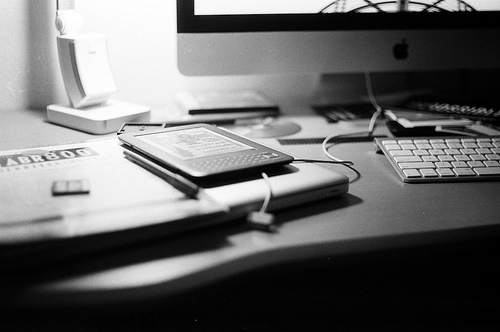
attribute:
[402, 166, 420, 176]
keys — white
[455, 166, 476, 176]
keys — white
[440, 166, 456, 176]
keys — white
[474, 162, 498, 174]
keys — white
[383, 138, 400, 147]
keys — white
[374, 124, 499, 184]
keyboard — light colored, computer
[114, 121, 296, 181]
tablet — black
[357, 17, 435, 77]
sign — apple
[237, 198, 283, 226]
charger — unused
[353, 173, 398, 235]
desk — grey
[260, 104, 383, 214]
cord — unused, charger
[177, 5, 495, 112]
computer monitor — black, white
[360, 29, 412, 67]
icon — Apple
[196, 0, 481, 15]
screen — powered, computer